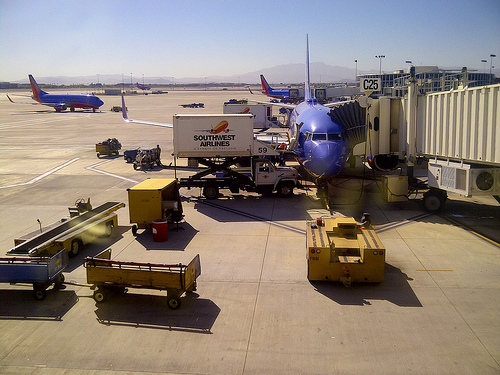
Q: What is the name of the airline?
A: Southwest Airlines.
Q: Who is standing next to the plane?
A: No one.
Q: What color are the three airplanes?
A: Blue.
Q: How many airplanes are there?
A: Three.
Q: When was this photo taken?
A: Daytime.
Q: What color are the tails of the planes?
A: Red.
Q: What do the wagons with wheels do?
A: Carry luggage.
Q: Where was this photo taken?
A: Airport.